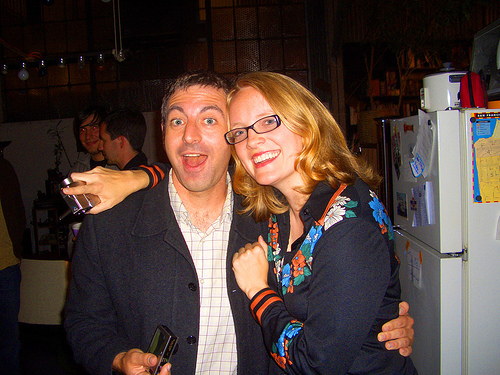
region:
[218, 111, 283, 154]
a woman wearin glasses.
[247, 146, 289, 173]
a woman's smile.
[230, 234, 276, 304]
a woman's hand.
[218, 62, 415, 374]
a middle aged woman.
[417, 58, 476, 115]
a crock pot on a fridge.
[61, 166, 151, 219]
a woman holding something.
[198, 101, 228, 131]
a man's left eye.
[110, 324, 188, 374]
a hand holding an electronic device.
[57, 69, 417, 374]
a couple.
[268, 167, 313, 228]
the female neck line.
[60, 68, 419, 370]
man and woman posing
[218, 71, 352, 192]
woman wearing black glasses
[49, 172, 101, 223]
silver camera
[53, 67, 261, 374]
man holding camera in hand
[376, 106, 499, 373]
white colored refrigerator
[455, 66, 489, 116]
red bag on top of refrigerator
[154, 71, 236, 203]
man with dark colored hair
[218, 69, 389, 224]
woman with light colored hair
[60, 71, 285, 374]
man wearing jacket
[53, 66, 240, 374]
man wearing white shirt with stripes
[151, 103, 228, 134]
Man has blue eyes.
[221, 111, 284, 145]
Woman is wearing glasses.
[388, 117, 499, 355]
The refrigerator is white.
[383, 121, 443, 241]
Papers and pictures on the refrigerator.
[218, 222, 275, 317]
Woman's hand is on man's chest.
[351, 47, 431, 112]
Books on a shelf in the background.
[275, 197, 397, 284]
Flowers on the woman's shirt.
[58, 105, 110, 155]
Person in the background looking at the camera.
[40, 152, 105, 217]
Woman is holding a digital camera.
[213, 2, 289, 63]
Brown tiles on the wall.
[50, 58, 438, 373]
A MAN AND A WOMAN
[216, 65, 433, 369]
A WOMAN WEARING A COLORFUL SHIRT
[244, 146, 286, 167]
A WOMAN'S MAXILLARY DENTITION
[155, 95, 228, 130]
VERY ARCHED EYE BROWS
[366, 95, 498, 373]
A WHITE REFRIDGERATOR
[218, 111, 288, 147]
A PAIR OF GLASSES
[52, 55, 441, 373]
A MAN AND WOMAN HOLDING EACH OTHER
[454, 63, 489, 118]
A RED AND BLACK CONTAINER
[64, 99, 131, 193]
A MAN WITH RED EYES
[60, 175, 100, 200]
A WOMAN'S POINTER FINGER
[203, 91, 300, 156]
A woman wearing eyeglasses.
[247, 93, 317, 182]
A woman wearing eyeglasses.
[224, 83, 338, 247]
A woman wearing eyeglasses.